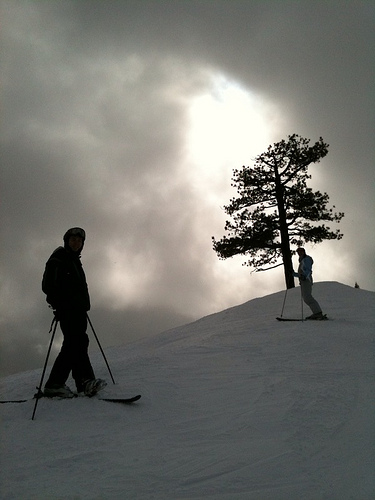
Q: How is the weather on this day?
A: It is cloudy.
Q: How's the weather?
A: It is cloudy.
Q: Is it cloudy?
A: Yes, it is cloudy.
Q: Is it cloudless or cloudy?
A: It is cloudy.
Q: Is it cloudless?
A: No, it is cloudy.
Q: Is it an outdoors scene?
A: Yes, it is outdoors.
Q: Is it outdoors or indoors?
A: It is outdoors.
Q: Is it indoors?
A: No, it is outdoors.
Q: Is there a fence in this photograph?
A: No, there are no fences.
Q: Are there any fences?
A: No, there are no fences.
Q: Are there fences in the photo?
A: No, there are no fences.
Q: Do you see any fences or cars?
A: No, there are no fences or cars.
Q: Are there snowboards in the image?
A: No, there are no snowboards.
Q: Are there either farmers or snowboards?
A: No, there are no snowboards or farmers.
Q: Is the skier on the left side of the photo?
A: Yes, the skier is on the left of the image.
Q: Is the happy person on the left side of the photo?
A: Yes, the skier is on the left of the image.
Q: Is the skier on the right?
A: No, the skier is on the left of the image.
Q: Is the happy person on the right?
A: No, the skier is on the left of the image.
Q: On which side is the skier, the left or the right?
A: The skier is on the left of the image.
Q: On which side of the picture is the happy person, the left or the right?
A: The skier is on the left of the image.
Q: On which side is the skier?
A: The skier is on the left of the image.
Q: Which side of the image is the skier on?
A: The skier is on the left of the image.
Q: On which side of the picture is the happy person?
A: The skier is on the left of the image.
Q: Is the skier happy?
A: Yes, the skier is happy.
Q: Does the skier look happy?
A: Yes, the skier is happy.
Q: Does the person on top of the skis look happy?
A: Yes, the skier is happy.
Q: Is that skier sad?
A: No, the skier is happy.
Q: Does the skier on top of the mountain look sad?
A: No, the skier is happy.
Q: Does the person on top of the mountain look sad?
A: No, the skier is happy.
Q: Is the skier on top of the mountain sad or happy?
A: The skier is happy.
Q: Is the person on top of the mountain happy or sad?
A: The skier is happy.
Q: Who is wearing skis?
A: The skier is wearing skis.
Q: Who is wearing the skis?
A: The skier is wearing skis.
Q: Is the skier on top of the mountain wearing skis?
A: Yes, the skier is wearing skis.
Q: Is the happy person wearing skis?
A: Yes, the skier is wearing skis.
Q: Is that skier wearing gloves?
A: No, the skier is wearing skis.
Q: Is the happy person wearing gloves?
A: No, the skier is wearing skis.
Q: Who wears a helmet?
A: The skier wears a helmet.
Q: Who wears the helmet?
A: The skier wears a helmet.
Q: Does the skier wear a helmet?
A: Yes, the skier wears a helmet.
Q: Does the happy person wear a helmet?
A: Yes, the skier wears a helmet.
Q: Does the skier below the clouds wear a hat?
A: No, the skier wears a helmet.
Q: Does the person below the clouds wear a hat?
A: No, the skier wears a helmet.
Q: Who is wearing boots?
A: The skier is wearing boots.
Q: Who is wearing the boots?
A: The skier is wearing boots.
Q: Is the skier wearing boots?
A: Yes, the skier is wearing boots.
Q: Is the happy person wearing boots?
A: Yes, the skier is wearing boots.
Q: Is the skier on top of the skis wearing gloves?
A: No, the skier is wearing boots.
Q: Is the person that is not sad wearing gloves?
A: No, the skier is wearing boots.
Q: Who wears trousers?
A: The skier wears trousers.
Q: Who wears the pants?
A: The skier wears trousers.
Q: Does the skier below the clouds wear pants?
A: Yes, the skier wears pants.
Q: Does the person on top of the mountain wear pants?
A: Yes, the skier wears pants.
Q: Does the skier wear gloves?
A: No, the skier wears pants.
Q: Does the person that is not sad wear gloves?
A: No, the skier wears pants.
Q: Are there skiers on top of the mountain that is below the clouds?
A: Yes, there is a skier on top of the mountain.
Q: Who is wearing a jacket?
A: The skier is wearing a jacket.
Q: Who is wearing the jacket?
A: The skier is wearing a jacket.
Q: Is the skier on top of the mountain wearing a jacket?
A: Yes, the skier is wearing a jacket.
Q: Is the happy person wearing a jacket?
A: Yes, the skier is wearing a jacket.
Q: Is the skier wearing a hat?
A: No, the skier is wearing a jacket.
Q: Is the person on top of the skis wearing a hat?
A: No, the skier is wearing a jacket.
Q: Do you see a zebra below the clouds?
A: No, there is a skier below the clouds.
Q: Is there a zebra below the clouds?
A: No, there is a skier below the clouds.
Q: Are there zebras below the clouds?
A: No, there is a skier below the clouds.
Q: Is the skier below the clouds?
A: Yes, the skier is below the clouds.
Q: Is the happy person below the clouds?
A: Yes, the skier is below the clouds.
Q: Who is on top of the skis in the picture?
A: The skier is on top of the skis.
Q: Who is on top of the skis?
A: The skier is on top of the skis.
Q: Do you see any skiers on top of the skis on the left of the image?
A: Yes, there is a skier on top of the skis.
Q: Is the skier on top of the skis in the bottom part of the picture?
A: Yes, the skier is on top of the skis.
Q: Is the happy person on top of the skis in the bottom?
A: Yes, the skier is on top of the skis.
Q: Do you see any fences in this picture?
A: No, there are no fences.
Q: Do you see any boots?
A: Yes, there are boots.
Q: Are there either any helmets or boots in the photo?
A: Yes, there are boots.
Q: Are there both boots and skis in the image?
A: Yes, there are both boots and skis.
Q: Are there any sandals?
A: No, there are no sandals.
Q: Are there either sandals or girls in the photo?
A: No, there are no sandals or girls.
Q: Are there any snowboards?
A: No, there are no snowboards.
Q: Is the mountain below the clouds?
A: Yes, the mountain is below the clouds.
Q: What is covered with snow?
A: The mountain is covered with snow.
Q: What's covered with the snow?
A: The mountain is covered with snow.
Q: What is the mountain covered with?
A: The mountain is covered with snow.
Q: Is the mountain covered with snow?
A: Yes, the mountain is covered with snow.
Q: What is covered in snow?
A: The mountain is covered in snow.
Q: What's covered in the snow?
A: The mountain is covered in snow.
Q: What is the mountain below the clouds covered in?
A: The mountain is covered in snow.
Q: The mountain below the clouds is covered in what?
A: The mountain is covered in snow.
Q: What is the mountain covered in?
A: The mountain is covered in snow.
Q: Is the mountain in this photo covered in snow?
A: Yes, the mountain is covered in snow.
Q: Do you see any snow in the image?
A: Yes, there is snow.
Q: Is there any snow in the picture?
A: Yes, there is snow.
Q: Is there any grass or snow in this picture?
A: Yes, there is snow.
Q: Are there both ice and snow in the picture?
A: No, there is snow but no ice.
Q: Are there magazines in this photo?
A: No, there are no magazines.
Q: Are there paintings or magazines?
A: No, there are no magazines or paintings.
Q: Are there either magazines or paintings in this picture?
A: No, there are no magazines or paintings.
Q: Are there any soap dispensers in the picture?
A: No, there are no soap dispensers.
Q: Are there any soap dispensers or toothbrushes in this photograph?
A: No, there are no soap dispensers or toothbrushes.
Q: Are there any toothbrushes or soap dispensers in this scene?
A: No, there are no soap dispensers or toothbrushes.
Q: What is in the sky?
A: The clouds are in the sky.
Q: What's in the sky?
A: The clouds are in the sky.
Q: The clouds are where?
A: The clouds are in the sky.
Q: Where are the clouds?
A: The clouds are in the sky.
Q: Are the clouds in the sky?
A: Yes, the clouds are in the sky.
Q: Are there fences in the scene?
A: No, there are no fences.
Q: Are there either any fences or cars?
A: No, there are no fences or cars.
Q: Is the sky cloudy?
A: Yes, the sky is cloudy.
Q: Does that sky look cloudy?
A: Yes, the sky is cloudy.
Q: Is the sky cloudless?
A: No, the sky is cloudy.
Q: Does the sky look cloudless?
A: No, the sky is cloudy.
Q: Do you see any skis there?
A: Yes, there are skis.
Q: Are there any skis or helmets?
A: Yes, there are skis.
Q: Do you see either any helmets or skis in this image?
A: Yes, there are skis.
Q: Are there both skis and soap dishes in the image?
A: No, there are skis but no soap dishes.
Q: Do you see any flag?
A: No, there are no flags.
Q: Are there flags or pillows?
A: No, there are no flags or pillows.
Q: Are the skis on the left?
A: Yes, the skis are on the left of the image.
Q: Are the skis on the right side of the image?
A: No, the skis are on the left of the image.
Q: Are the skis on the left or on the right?
A: The skis are on the left of the image.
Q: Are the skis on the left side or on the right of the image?
A: The skis are on the left of the image.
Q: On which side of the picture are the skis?
A: The skis are on the left of the image.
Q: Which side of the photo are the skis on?
A: The skis are on the left of the image.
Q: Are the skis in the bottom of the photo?
A: Yes, the skis are in the bottom of the image.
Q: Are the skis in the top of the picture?
A: No, the skis are in the bottom of the image.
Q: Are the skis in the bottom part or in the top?
A: The skis are in the bottom of the image.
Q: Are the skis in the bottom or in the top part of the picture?
A: The skis are in the bottom of the image.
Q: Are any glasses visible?
A: No, there are no glasses.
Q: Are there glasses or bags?
A: No, there are no glasses or bags.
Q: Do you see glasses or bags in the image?
A: No, there are no glasses or bags.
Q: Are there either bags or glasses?
A: No, there are no glasses or bags.